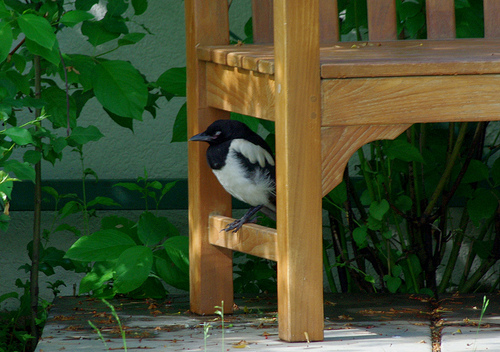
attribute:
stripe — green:
[7, 174, 191, 216]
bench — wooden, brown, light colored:
[177, 0, 498, 345]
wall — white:
[0, 3, 355, 330]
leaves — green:
[34, 36, 147, 148]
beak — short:
[185, 132, 214, 144]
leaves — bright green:
[4, 0, 160, 186]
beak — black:
[186, 121, 210, 159]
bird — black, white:
[188, 115, 285, 237]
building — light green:
[10, 5, 499, 239]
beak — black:
[188, 124, 217, 149]